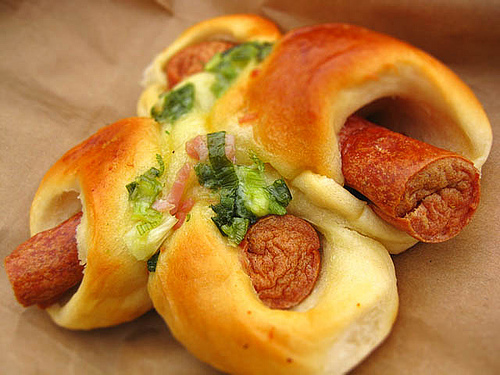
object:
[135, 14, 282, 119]
croissant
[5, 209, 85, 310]
hotdog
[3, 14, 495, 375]
appetizer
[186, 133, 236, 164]
tomato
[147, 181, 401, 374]
croissant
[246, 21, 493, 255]
sections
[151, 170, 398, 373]
sections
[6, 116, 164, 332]
sections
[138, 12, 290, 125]
sections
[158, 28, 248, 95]
hole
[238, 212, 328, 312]
hole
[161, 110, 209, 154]
melted cheese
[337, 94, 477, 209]
hole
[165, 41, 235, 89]
hotdog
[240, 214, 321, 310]
hotdog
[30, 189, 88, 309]
hole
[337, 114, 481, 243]
hot dog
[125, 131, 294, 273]
garnish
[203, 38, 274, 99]
garnish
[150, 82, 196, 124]
garnish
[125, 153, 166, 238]
hole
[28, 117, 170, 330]
croissant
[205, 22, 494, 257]
croissant